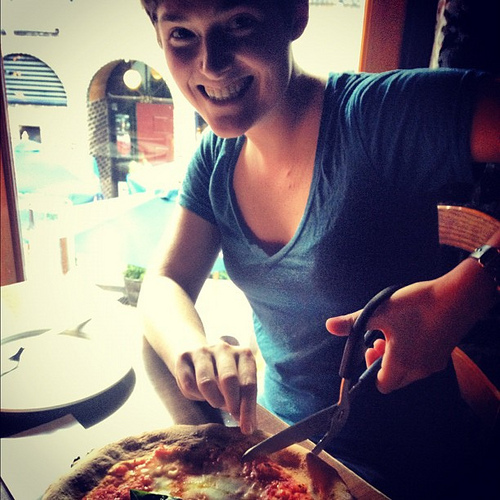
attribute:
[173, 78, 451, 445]
shirt — blue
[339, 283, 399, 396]
handles — black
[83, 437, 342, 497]
pizza — small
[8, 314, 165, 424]
plate — white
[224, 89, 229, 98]
tooth — white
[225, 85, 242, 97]
tooth — white